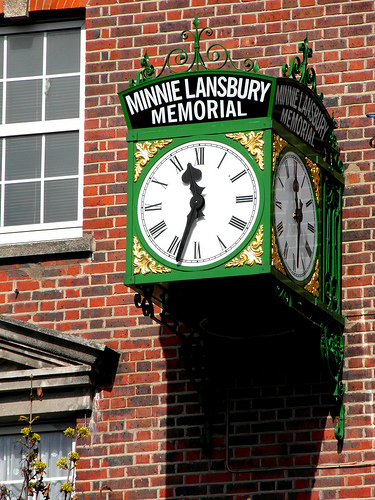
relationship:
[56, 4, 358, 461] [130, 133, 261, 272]
picture of clock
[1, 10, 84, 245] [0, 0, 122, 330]
window on building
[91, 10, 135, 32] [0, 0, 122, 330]
red brick building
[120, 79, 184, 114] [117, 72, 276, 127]
minnie in lettering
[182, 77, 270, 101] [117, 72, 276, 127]
lansbury in white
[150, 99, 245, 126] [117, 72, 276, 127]
memorial in lettering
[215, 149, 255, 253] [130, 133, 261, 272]
numerals on clock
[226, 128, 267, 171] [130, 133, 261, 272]
design on clock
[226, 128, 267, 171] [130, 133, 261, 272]
design of clock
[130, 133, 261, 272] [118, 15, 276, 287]
clock on green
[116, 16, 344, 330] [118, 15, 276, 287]
item mostly item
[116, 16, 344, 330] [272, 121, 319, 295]
item has watch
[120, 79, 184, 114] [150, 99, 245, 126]
minnie lansbury memorial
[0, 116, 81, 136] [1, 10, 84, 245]
wood above window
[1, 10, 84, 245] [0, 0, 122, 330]
window in building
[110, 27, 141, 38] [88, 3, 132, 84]
brick in wall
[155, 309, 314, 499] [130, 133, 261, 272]
shadow under clock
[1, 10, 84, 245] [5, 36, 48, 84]
eight window panes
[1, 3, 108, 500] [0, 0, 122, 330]
wall with windows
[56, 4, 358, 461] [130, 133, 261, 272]
wall with clock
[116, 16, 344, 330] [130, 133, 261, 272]
decorative memorial clock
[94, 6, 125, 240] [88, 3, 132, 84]
dark brick wall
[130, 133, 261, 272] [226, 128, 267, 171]
clock with gold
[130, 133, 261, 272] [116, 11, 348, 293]
clock on wall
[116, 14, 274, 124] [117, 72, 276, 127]
sign honoring woman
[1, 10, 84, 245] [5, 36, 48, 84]
divided by panes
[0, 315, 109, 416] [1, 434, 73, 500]
molding over window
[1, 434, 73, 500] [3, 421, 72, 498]
curtains hanging in window